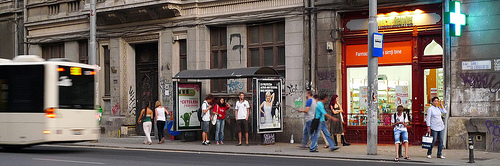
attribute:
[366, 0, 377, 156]
pole — tall, gray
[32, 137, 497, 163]
sidewalk — long